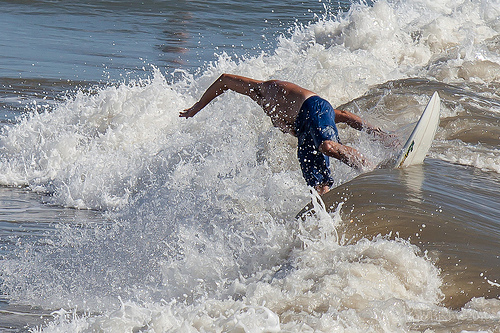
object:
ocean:
[5, 5, 494, 330]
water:
[0, 2, 480, 323]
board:
[393, 90, 440, 168]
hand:
[368, 133, 401, 150]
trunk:
[293, 97, 338, 187]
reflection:
[402, 163, 424, 211]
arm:
[197, 73, 258, 114]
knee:
[318, 138, 339, 157]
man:
[177, 73, 402, 198]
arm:
[335, 108, 389, 148]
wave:
[0, 0, 499, 330]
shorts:
[294, 96, 341, 190]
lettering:
[397, 140, 416, 169]